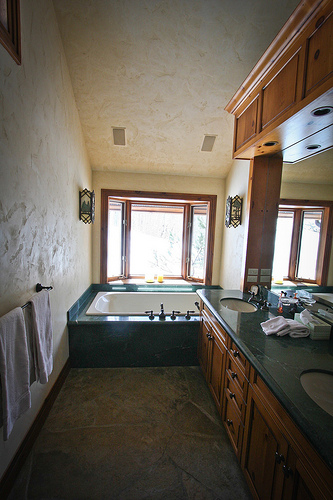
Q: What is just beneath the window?
A: A bathtub.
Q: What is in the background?
A: A window.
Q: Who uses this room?
A: People who bathe.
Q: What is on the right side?
A: Two sinks.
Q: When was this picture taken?
A: During the day.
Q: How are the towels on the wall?
A: They are held by a towel rack.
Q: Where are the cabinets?
A: Beneath the sinks.